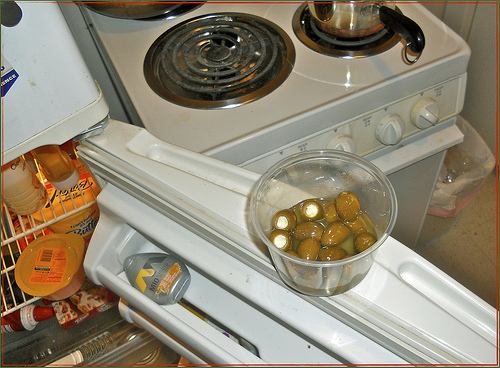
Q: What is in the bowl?
A: Olive.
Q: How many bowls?
A: 1.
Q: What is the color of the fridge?
A: White.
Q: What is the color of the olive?
A: Green.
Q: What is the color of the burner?
A: Grey.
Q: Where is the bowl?
A: In the fridge door.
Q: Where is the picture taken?
A: In the kitchen.